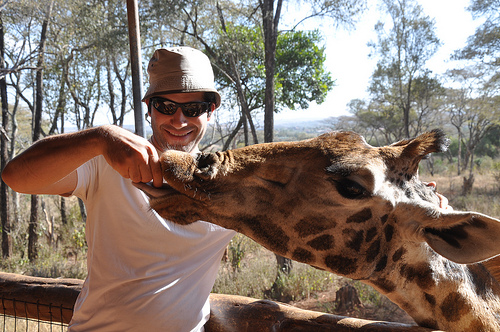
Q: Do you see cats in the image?
A: No, there are no cats.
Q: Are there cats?
A: No, there are no cats.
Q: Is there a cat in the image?
A: No, there are no cats.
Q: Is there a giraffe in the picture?
A: Yes, there is a giraffe.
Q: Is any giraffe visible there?
A: Yes, there is a giraffe.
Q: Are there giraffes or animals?
A: Yes, there is a giraffe.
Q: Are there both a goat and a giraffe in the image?
A: No, there is a giraffe but no goats.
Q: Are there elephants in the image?
A: No, there are no elephants.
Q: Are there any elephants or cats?
A: No, there are no elephants or cats.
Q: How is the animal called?
A: The animal is a giraffe.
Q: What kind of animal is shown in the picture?
A: The animal is a giraffe.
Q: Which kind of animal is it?
A: The animal is a giraffe.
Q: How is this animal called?
A: That is a giraffe.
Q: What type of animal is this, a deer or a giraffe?
A: That is a giraffe.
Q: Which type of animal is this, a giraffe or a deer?
A: That is a giraffe.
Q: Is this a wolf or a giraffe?
A: This is a giraffe.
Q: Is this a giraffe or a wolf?
A: This is a giraffe.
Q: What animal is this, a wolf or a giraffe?
A: This is a giraffe.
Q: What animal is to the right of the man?
A: The animal is a giraffe.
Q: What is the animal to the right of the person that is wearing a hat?
A: The animal is a giraffe.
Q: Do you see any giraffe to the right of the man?
A: Yes, there is a giraffe to the right of the man.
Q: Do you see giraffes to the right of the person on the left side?
A: Yes, there is a giraffe to the right of the man.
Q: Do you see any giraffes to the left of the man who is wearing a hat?
A: No, the giraffe is to the right of the man.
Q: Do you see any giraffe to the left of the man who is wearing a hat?
A: No, the giraffe is to the right of the man.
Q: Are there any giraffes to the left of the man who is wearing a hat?
A: No, the giraffe is to the right of the man.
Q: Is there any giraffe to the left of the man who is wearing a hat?
A: No, the giraffe is to the right of the man.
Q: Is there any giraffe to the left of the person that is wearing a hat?
A: No, the giraffe is to the right of the man.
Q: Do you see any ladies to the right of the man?
A: No, there is a giraffe to the right of the man.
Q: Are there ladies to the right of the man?
A: No, there is a giraffe to the right of the man.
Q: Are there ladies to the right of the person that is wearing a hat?
A: No, there is a giraffe to the right of the man.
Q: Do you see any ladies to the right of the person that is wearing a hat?
A: No, there is a giraffe to the right of the man.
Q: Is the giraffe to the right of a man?
A: Yes, the giraffe is to the right of a man.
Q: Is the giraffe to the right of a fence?
A: No, the giraffe is to the right of a man.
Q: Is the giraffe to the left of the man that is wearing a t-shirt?
A: No, the giraffe is to the right of the man.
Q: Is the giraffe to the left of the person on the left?
A: No, the giraffe is to the right of the man.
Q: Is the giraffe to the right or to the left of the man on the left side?
A: The giraffe is to the right of the man.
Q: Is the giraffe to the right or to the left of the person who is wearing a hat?
A: The giraffe is to the right of the man.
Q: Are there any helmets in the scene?
A: No, there are no helmets.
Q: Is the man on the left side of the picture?
A: Yes, the man is on the left of the image.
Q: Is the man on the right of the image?
A: No, the man is on the left of the image.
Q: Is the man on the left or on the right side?
A: The man is on the left of the image.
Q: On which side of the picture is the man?
A: The man is on the left of the image.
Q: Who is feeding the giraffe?
A: The man is feeding the giraffe.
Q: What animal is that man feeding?
A: The man is feeding the giraffe.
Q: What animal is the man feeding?
A: The man is feeding the giraffe.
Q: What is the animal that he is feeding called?
A: The animal is a giraffe.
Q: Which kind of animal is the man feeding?
A: The man is feeding the giraffe.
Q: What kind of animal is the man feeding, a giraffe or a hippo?
A: The man is feeding a giraffe.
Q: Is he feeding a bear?
A: No, the man is feeding the giraffe.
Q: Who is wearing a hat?
A: The man is wearing a hat.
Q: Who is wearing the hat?
A: The man is wearing a hat.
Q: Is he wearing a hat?
A: Yes, the man is wearing a hat.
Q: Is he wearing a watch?
A: No, the man is wearing a hat.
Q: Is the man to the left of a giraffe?
A: Yes, the man is to the left of a giraffe.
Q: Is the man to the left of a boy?
A: No, the man is to the left of a giraffe.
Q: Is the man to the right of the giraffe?
A: No, the man is to the left of the giraffe.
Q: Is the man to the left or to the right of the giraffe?
A: The man is to the left of the giraffe.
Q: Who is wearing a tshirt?
A: The man is wearing a tshirt.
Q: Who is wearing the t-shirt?
A: The man is wearing a tshirt.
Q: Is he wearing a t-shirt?
A: Yes, the man is wearing a t-shirt.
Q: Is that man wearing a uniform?
A: No, the man is wearing a t-shirt.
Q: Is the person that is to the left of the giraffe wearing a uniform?
A: No, the man is wearing a t-shirt.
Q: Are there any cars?
A: No, there are no cars.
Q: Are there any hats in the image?
A: Yes, there is a hat.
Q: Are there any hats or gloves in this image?
A: Yes, there is a hat.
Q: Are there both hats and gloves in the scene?
A: No, there is a hat but no gloves.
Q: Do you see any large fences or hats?
A: Yes, there is a large hat.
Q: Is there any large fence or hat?
A: Yes, there is a large hat.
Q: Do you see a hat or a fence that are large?
A: Yes, the hat is large.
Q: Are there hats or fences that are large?
A: Yes, the hat is large.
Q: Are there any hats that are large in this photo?
A: Yes, there is a large hat.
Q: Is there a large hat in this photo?
A: Yes, there is a large hat.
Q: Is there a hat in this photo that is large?
A: Yes, there is a hat that is large.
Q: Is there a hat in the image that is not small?
A: Yes, there is a large hat.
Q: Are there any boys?
A: No, there are no boys.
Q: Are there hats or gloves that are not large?
A: No, there is a hat but it is large.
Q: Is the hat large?
A: Yes, the hat is large.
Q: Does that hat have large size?
A: Yes, the hat is large.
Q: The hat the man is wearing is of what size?
A: The hat is large.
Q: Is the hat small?
A: No, the hat is large.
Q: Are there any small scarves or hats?
A: No, there is a hat but it is large.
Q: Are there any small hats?
A: No, there is a hat but it is large.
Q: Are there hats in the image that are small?
A: No, there is a hat but it is large.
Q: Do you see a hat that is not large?
A: No, there is a hat but it is large.